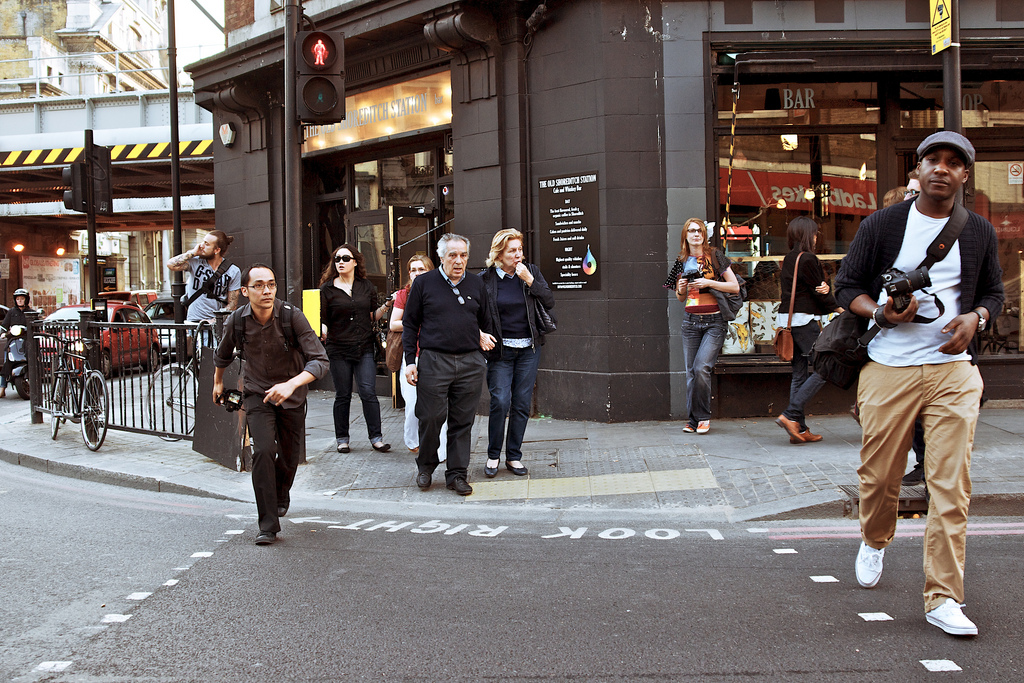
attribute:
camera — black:
[877, 258, 938, 313]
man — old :
[397, 223, 491, 502]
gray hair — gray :
[434, 229, 474, 264]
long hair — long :
[317, 242, 372, 290]